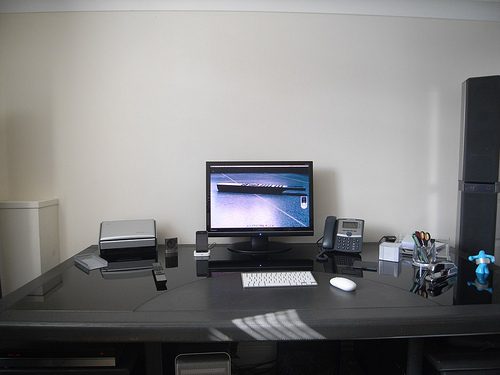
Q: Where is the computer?
A: On a desk.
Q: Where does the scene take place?
A: In an office.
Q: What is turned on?
A: Computer screen.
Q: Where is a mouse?
A: To the right of the keyboard.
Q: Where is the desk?
A: Against the wall.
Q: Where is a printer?
A: To the left of the computer.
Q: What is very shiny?
A: The desk.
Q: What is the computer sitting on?
A: The black desk.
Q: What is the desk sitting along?
A: A white wall.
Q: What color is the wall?
A: White.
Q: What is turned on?
A: The computer.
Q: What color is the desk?
A: Black.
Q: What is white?
A: The keyboard and mouse.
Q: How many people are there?
A: None.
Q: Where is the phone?
A: Next to the computer.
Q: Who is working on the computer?
A: No one.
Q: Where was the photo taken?
A: In his office.